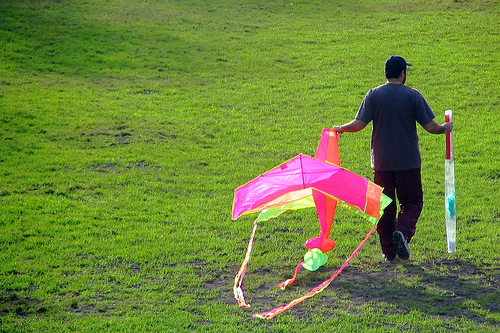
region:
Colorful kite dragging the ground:
[221, 120, 394, 321]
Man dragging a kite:
[221, 55, 474, 321]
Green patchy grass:
[28, 103, 278, 324]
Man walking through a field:
[321, 55, 473, 280]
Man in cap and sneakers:
[329, 54, 467, 273]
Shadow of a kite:
[322, 253, 469, 331]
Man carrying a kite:
[328, 54, 463, 285]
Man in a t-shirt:
[332, 55, 460, 270]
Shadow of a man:
[403, 257, 498, 329]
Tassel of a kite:
[228, 219, 268, 311]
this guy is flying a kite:
[195, 38, 475, 311]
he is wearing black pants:
[364, 50, 445, 277]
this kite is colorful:
[228, 126, 380, 314]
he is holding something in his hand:
[435, 108, 479, 253]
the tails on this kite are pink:
[228, 218, 381, 315]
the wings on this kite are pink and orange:
[226, 156, 386, 218]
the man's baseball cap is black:
[370, 48, 425, 85]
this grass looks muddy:
[14, 183, 224, 318]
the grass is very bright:
[265, 16, 495, 96]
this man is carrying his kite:
[240, 113, 384, 314]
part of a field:
[123, 195, 161, 257]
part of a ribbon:
[322, 279, 367, 309]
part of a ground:
[198, 264, 223, 299]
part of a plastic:
[441, 188, 463, 225]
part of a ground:
[108, 228, 159, 270]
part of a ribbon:
[283, 271, 316, 303]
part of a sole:
[375, 227, 415, 265]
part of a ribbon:
[296, 279, 326, 301]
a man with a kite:
[226, 51, 461, 322]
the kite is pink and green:
[225, 125, 395, 321]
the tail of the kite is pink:
[231, 223, 377, 323]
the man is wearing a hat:
[379, 51, 414, 81]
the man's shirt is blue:
[354, 83, 434, 171]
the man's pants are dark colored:
[369, 168, 424, 256]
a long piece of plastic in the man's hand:
[441, 106, 461, 253]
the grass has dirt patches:
[0, 100, 499, 327]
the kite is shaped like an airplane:
[229, 124, 392, 321]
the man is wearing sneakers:
[377, 228, 411, 265]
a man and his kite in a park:
[214, 43, 476, 324]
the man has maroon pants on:
[371, 168, 426, 250]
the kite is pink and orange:
[225, 121, 390, 318]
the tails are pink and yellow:
[227, 215, 377, 321]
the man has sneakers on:
[380, 225, 411, 262]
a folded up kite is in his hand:
[437, 100, 472, 262]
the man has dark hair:
[383, 52, 408, 88]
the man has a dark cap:
[380, 42, 415, 73]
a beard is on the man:
[396, 62, 407, 85]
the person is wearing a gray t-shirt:
[351, 80, 430, 176]